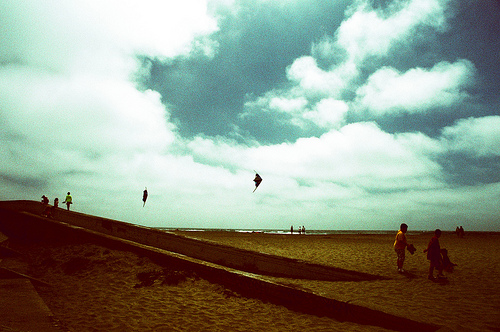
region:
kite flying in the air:
[247, 169, 268, 201]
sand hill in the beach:
[22, 199, 320, 316]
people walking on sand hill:
[33, 181, 93, 229]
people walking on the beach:
[387, 216, 464, 291]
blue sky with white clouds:
[285, 41, 420, 184]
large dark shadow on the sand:
[100, 239, 360, 321]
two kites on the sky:
[129, 162, 292, 224]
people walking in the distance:
[280, 213, 335, 244]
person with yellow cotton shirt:
[392, 227, 410, 259]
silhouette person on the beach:
[422, 223, 465, 288]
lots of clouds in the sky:
[59, 23, 410, 157]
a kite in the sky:
[250, 165, 267, 197]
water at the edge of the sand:
[244, 226, 287, 234]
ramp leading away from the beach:
[16, 196, 222, 273]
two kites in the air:
[129, 168, 270, 208]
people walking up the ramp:
[34, 185, 78, 217]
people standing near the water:
[285, 220, 311, 238]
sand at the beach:
[87, 295, 199, 329]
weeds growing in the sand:
[130, 263, 185, 293]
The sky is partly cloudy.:
[54, 18, 485, 195]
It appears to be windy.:
[10, 26, 452, 327]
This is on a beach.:
[11, 15, 435, 327]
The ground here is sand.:
[76, 278, 194, 326]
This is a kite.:
[185, 134, 301, 199]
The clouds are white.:
[23, 21, 140, 150]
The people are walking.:
[363, 198, 486, 310]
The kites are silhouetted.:
[114, 142, 287, 207]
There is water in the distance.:
[183, 208, 380, 248]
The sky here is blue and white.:
[230, 20, 490, 173]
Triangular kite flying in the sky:
[249, 168, 264, 191]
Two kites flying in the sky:
[136, 168, 263, 209]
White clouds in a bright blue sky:
[0, 1, 497, 233]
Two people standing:
[392, 222, 446, 279]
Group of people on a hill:
[39, 189, 72, 220]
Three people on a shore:
[287, 221, 309, 235]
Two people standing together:
[452, 223, 467, 238]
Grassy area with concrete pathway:
[2, 197, 499, 327]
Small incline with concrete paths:
[1, 196, 441, 328]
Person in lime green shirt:
[61, 189, 74, 211]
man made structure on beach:
[16, 193, 388, 326]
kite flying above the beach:
[246, 167, 281, 205]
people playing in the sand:
[383, 205, 464, 294]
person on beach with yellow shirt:
[384, 218, 419, 278]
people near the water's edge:
[269, 215, 324, 241]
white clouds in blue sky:
[38, 35, 387, 163]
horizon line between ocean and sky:
[203, 221, 452, 238]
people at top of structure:
[21, 189, 181, 216]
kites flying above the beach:
[113, 161, 289, 223]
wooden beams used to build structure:
[104, 225, 397, 302]